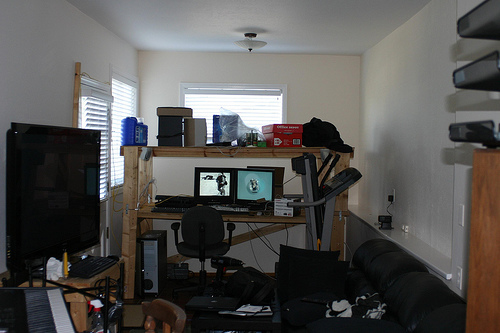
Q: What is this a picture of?
A: Home office.